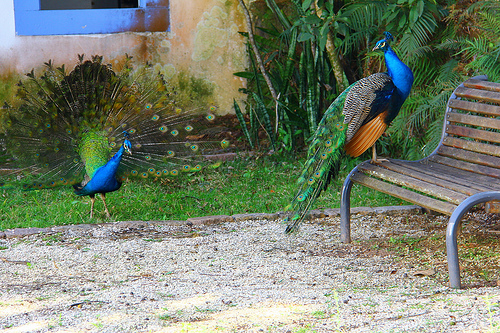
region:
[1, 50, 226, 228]
Male peacock with tail feathers extended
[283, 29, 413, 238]
Peacock with tail feathers relaxed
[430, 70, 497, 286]
Bench with metal legs and wooden slats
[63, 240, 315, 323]
Light color gravel surface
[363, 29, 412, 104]
Peacock looking behind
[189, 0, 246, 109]
Outdoor wall with algae stains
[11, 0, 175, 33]
Blue outdoor window frame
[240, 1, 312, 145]
Tropical plants outdoor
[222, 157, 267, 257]
Grass next to gravel area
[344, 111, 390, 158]
Orange feathers on peacock wing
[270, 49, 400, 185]
a peacock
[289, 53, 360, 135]
a peacock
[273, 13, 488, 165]
a peacock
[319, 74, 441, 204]
a peacock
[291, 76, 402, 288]
a peacock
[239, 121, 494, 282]
a peacock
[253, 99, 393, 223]
a peacock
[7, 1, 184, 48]
Wood trimmed window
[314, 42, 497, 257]
Wooden bench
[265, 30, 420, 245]
Peacock standing on the bench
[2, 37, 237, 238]
Peacock with his tail open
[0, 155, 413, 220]
Grassy area by the building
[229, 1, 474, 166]
Trees by the building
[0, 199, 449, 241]
Stone divider between grass and walkway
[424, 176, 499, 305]
Closest metal leg on the bench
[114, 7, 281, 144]
Damage on the side of the building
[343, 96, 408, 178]
Bright orange area on the peacock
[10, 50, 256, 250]
peacock displaying its feathers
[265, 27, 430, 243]
peacock on the bench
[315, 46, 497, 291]
wood and metal bench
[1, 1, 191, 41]
blue window frame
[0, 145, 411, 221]
patch of green grass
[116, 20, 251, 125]
dirty stained mossy wall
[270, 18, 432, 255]
peacock looking behind itself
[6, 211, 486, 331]
gravel pathway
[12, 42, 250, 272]
peacock standing in the grass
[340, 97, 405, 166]
orange feathers on the peacock's wing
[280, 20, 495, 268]
peacock standing on a bench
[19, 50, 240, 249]
peacock standing on the ground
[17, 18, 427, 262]
two peacocks standing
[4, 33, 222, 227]
peacock with its feathers extended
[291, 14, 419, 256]
blue chested peacock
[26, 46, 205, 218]
blue chested peacock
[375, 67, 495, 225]
wooden and metal bench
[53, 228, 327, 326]
small pebbles on the ground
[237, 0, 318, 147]
green plants behind peacocks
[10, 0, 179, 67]
window on a building